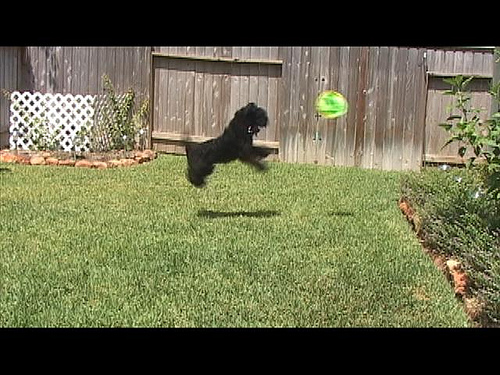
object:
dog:
[181, 102, 280, 188]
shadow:
[197, 209, 279, 217]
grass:
[0, 153, 474, 327]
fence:
[0, 45, 498, 174]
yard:
[0, 20, 500, 329]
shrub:
[402, 168, 500, 295]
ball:
[313, 90, 349, 121]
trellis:
[9, 91, 132, 153]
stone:
[142, 149, 158, 158]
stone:
[121, 159, 139, 165]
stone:
[74, 159, 94, 168]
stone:
[45, 156, 60, 164]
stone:
[0, 152, 17, 164]